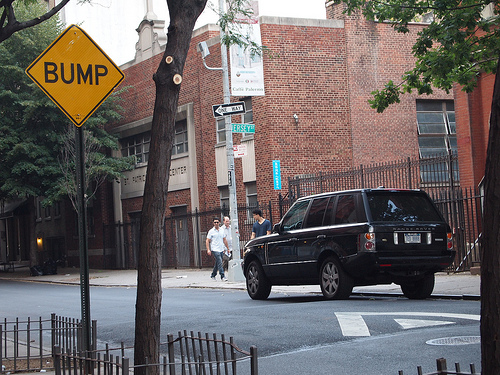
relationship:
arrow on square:
[214, 101, 244, 117] [208, 100, 245, 118]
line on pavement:
[393, 315, 456, 332] [2, 276, 482, 373]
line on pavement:
[331, 309, 481, 339] [2, 276, 482, 373]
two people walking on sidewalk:
[204, 206, 225, 284] [0, 265, 479, 296]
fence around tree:
[125, 0, 230, 374] [133, 0, 206, 370]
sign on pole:
[25, 24, 126, 127] [73, 127, 94, 370]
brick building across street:
[4, 0, 499, 272] [0, 277, 483, 373]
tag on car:
[363, 228, 436, 257] [241, 187, 456, 300]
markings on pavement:
[335, 311, 480, 338] [2, 276, 482, 373]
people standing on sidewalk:
[205, 207, 270, 269] [166, 261, 205, 283]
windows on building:
[417, 107, 461, 179] [98, 4, 475, 265]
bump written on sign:
[44, 61, 108, 85] [21, 20, 128, 130]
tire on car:
[319, 257, 355, 300] [211, 183, 461, 303]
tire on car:
[399, 272, 435, 300] [211, 183, 461, 303]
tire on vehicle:
[244, 257, 269, 299] [229, 189, 457, 316]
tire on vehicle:
[317, 257, 355, 310] [229, 189, 457, 316]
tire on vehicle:
[393, 272, 439, 306] [229, 189, 457, 316]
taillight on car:
[357, 231, 377, 252] [241, 185, 456, 300]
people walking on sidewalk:
[191, 203, 246, 282] [65, 264, 482, 308]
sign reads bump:
[25, 24, 126, 127] [42, 60, 107, 87]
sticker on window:
[385, 195, 398, 213] [366, 190, 434, 220]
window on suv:
[366, 190, 434, 220] [231, 227, 442, 288]